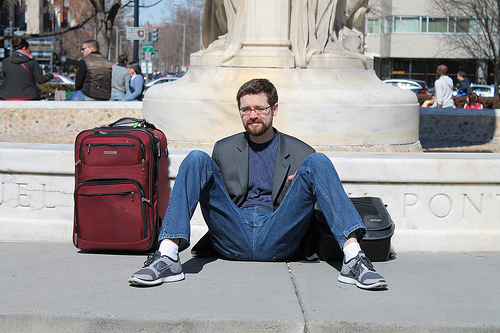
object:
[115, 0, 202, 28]
sky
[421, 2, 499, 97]
trees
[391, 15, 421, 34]
window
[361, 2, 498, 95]
building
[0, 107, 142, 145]
rocks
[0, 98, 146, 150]
wall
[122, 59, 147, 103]
woman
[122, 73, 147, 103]
shirt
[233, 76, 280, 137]
head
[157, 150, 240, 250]
leg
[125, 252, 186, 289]
feet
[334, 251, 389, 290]
feet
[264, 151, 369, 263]
leg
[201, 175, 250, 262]
thigh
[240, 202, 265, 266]
croch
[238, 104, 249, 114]
eye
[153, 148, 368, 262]
jeans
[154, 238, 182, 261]
sock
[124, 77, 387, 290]
man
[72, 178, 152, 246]
compartment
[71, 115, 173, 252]
suitcase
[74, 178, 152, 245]
storage compartment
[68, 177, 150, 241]
zipper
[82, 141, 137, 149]
zipper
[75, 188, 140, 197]
zipper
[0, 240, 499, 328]
floor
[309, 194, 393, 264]
luggage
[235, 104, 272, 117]
glasses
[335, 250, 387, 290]
shoe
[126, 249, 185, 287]
shoe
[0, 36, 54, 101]
person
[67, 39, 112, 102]
person